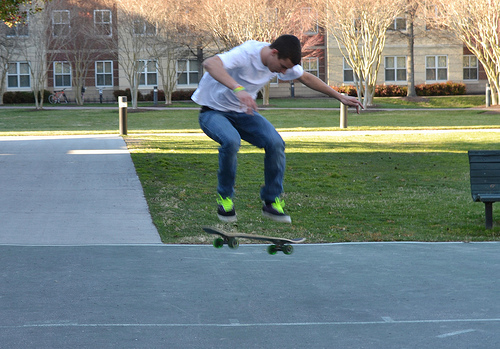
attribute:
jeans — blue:
[197, 105, 287, 197]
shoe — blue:
[263, 200, 300, 225]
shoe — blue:
[217, 189, 239, 222]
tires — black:
[208, 230, 245, 254]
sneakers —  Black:
[218, 182, 293, 224]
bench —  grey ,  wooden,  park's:
[462, 144, 497, 230]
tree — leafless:
[371, 5, 493, 98]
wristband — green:
[230, 76, 255, 99]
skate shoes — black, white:
[200, 168, 317, 251]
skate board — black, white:
[188, 202, 325, 273]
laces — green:
[196, 193, 254, 215]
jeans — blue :
[199, 106, 284, 201]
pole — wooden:
[115, 88, 130, 139]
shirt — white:
[170, 22, 285, 129]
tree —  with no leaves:
[310, 5, 413, 107]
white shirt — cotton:
[191, 37, 303, 114]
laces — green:
[215, 194, 238, 214]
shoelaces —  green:
[220, 193, 230, 211]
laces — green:
[270, 194, 286, 214]